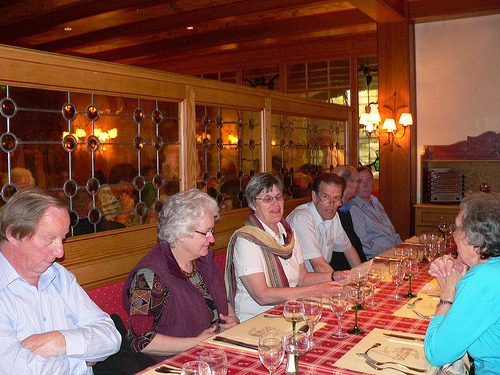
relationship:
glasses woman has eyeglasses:
[121, 188, 241, 364] [195, 228, 215, 238]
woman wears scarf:
[224, 172, 353, 324] [235, 211, 299, 286]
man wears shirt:
[285, 172, 362, 273] [285, 201, 355, 282]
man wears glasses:
[285, 172, 362, 273] [315, 189, 343, 201]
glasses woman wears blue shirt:
[423, 191, 500, 375] [423, 257, 500, 374]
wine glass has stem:
[402, 259, 418, 299] [405, 277, 415, 298]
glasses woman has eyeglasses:
[121, 188, 241, 364] [186, 221, 213, 240]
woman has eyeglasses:
[224, 172, 353, 324] [252, 191, 283, 208]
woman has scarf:
[227, 171, 315, 339] [222, 212, 297, 308]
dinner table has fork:
[134, 234, 471, 375] [363, 354, 429, 374]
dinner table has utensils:
[134, 234, 471, 375] [360, 352, 429, 371]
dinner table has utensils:
[134, 234, 471, 375] [355, 342, 382, 355]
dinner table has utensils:
[134, 234, 471, 375] [385, 329, 426, 342]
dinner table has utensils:
[134, 234, 471, 375] [152, 362, 186, 371]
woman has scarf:
[224, 172, 353, 324] [241, 213, 300, 288]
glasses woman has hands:
[423, 191, 500, 375] [417, 257, 499, 310]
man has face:
[264, 183, 359, 284] [318, 197, 378, 229]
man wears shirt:
[0, 190, 122, 375] [1, 250, 141, 373]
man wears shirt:
[285, 172, 362, 273] [285, 201, 358, 296]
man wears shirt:
[2, 190, 122, 370] [0, 242, 125, 373]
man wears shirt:
[2, 190, 122, 370] [2, 253, 122, 373]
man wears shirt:
[0, 190, 122, 375] [3, 273, 125, 372]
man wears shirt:
[0, 190, 122, 375] [0, 267, 118, 371]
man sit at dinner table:
[285, 172, 362, 273] [134, 219, 464, 372]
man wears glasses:
[285, 172, 362, 273] [311, 190, 342, 207]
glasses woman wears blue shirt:
[423, 191, 500, 375] [425, 250, 498, 372]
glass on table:
[300, 293, 323, 353] [140, 226, 460, 370]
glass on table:
[326, 287, 351, 337] [140, 226, 460, 370]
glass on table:
[388, 257, 406, 298] [140, 226, 460, 370]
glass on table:
[422, 238, 439, 271] [140, 226, 460, 370]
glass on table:
[257, 333, 287, 368] [140, 226, 460, 370]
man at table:
[285, 172, 362, 273] [140, 226, 460, 370]